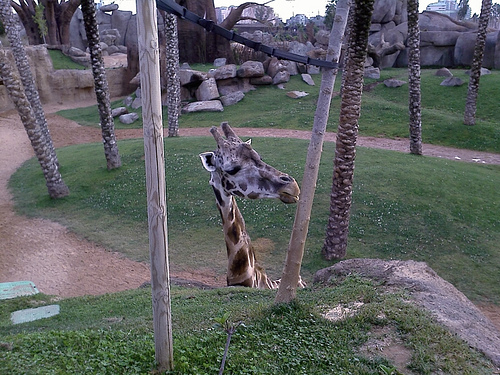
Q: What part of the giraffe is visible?
A: Neck and head.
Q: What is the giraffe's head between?
A: Two trees.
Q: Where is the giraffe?
A: In an enclosure.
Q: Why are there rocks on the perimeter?
A: To keep the giraffe inside.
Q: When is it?
A: Day time.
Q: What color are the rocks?
A: Grey.